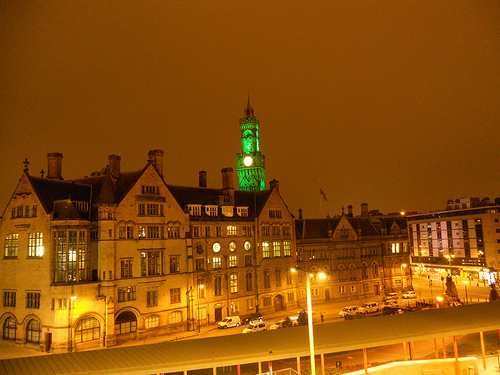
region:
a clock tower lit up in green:
[224, 87, 288, 189]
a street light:
[293, 266, 338, 299]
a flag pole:
[308, 173, 331, 220]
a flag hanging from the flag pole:
[321, 189, 329, 204]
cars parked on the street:
[339, 296, 382, 320]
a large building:
[8, 151, 298, 342]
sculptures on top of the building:
[16, 153, 53, 183]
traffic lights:
[425, 261, 490, 297]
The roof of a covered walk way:
[13, 300, 498, 372]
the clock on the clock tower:
[239, 157, 259, 167]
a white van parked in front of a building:
[218, 311, 242, 332]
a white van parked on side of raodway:
[212, 310, 244, 340]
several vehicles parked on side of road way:
[325, 284, 422, 322]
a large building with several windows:
[4, 147, 426, 372]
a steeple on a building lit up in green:
[223, 93, 278, 202]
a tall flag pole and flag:
[308, 177, 335, 224]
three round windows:
[206, 238, 253, 254]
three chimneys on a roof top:
[28, 152, 186, 186]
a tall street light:
[266, 245, 333, 372]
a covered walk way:
[272, 301, 478, 373]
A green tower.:
[221, 82, 281, 204]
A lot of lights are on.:
[23, 227, 345, 329]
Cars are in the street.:
[208, 274, 424, 338]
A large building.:
[7, 146, 292, 353]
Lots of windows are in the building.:
[9, 152, 292, 357]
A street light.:
[280, 259, 345, 374]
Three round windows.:
[206, 233, 257, 258]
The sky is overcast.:
[320, 49, 449, 166]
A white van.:
[208, 307, 250, 334]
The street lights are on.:
[279, 261, 339, 373]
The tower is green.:
[234, 93, 266, 187]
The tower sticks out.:
[236, 82, 266, 191]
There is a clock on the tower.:
[234, 153, 261, 168]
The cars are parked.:
[336, 299, 396, 314]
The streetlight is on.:
[288, 266, 333, 374]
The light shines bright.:
[292, 268, 322, 374]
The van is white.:
[219, 314, 241, 327]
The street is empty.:
[454, 283, 486, 293]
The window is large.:
[49, 222, 89, 280]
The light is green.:
[236, 115, 265, 192]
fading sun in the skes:
[271, 74, 398, 224]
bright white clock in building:
[209, 145, 266, 173]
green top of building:
[222, 108, 307, 215]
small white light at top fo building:
[389, 203, 421, 228]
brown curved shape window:
[64, 317, 106, 354]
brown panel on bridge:
[345, 335, 433, 364]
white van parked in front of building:
[221, 313, 272, 329]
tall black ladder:
[175, 232, 204, 325]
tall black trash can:
[29, 327, 62, 347]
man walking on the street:
[317, 305, 331, 331]